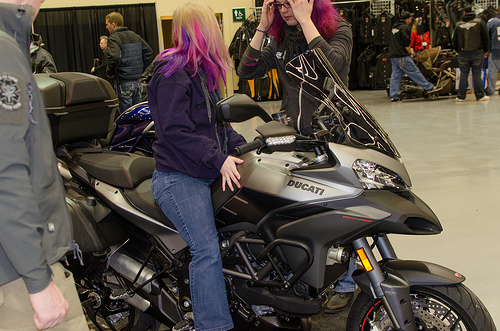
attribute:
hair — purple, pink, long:
[158, 3, 238, 83]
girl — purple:
[163, 20, 266, 323]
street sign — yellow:
[355, 245, 375, 272]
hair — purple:
[149, 0, 238, 86]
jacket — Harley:
[450, 17, 492, 56]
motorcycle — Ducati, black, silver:
[33, 46, 496, 328]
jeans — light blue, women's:
[150, 168, 236, 328]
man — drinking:
[98, 13, 155, 113]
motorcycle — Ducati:
[58, 71, 498, 319]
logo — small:
[277, 175, 326, 196]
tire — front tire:
[334, 260, 462, 322]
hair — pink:
[154, 14, 243, 90]